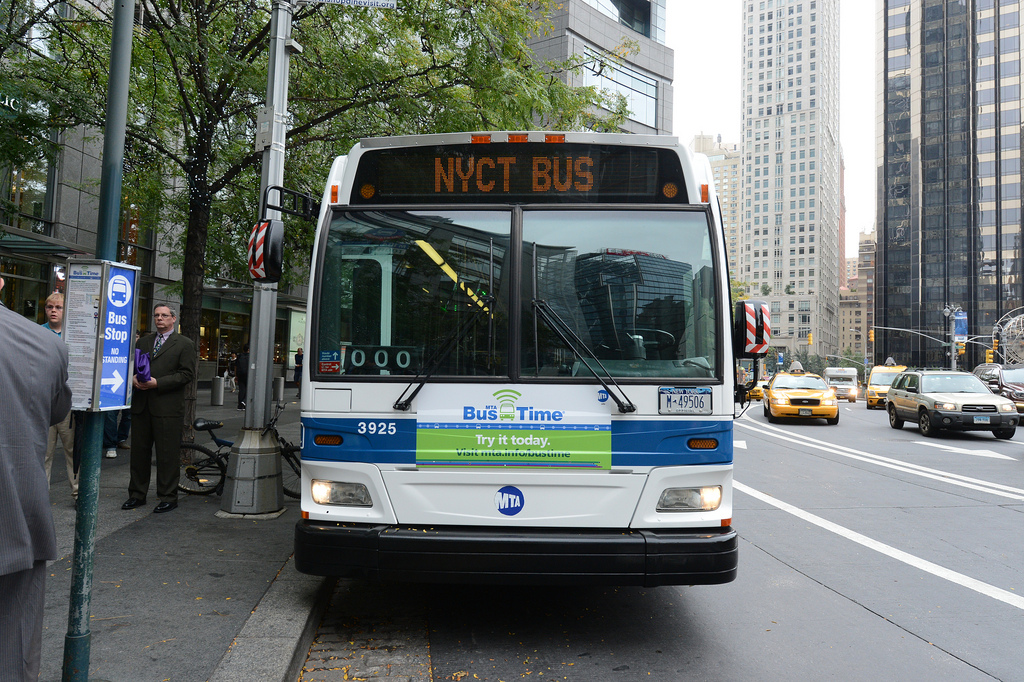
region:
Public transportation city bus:
[295, 130, 744, 584]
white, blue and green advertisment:
[413, 387, 611, 467]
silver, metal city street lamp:
[213, 1, 293, 518]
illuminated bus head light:
[309, 477, 373, 509]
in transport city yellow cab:
[762, 357, 842, 424]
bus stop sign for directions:
[65, 254, 136, 414]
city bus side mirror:
[738, 297, 773, 355]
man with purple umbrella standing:
[121, 302, 201, 512]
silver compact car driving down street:
[881, 367, 1021, 441]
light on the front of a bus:
[655, 480, 722, 512]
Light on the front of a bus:
[304, 474, 377, 516]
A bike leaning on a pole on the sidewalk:
[168, 405, 311, 504]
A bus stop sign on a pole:
[55, 256, 135, 413]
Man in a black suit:
[117, 300, 193, 520]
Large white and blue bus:
[291, 124, 741, 593]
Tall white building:
[735, 2, 840, 379]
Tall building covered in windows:
[870, 0, 1022, 392]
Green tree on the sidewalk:
[1, 6, 637, 456]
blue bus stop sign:
[105, 257, 135, 409]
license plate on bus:
[656, 383, 715, 416]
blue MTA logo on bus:
[491, 478, 543, 523]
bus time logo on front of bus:
[457, 387, 574, 427]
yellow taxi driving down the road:
[767, 349, 847, 435]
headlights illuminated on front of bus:
[303, 472, 731, 521]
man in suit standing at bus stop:
[144, 300, 202, 525]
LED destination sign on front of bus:
[416, 145, 613, 203]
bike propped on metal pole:
[181, 408, 311, 519]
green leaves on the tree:
[347, 66, 440, 153]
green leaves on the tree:
[190, 44, 223, 87]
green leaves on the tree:
[141, 59, 171, 92]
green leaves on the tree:
[511, 85, 588, 146]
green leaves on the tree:
[386, 62, 462, 120]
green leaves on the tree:
[461, 53, 550, 136]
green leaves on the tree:
[217, 103, 298, 173]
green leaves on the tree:
[220, 193, 278, 250]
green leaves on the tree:
[44, 48, 128, 175]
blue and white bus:
[299, 124, 742, 583]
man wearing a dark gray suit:
[125, 303, 202, 522]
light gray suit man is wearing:
[0, 303, 76, 680]